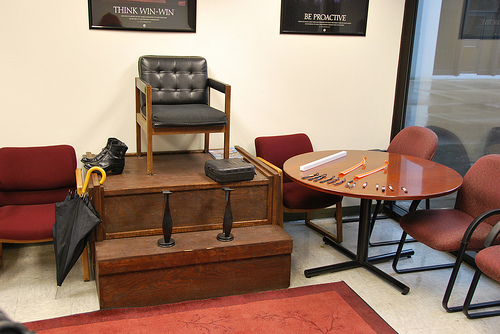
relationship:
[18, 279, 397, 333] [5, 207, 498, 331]
carpet on ground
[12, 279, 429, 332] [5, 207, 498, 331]
carpet on ground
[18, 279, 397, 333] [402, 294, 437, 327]
carpet on ground